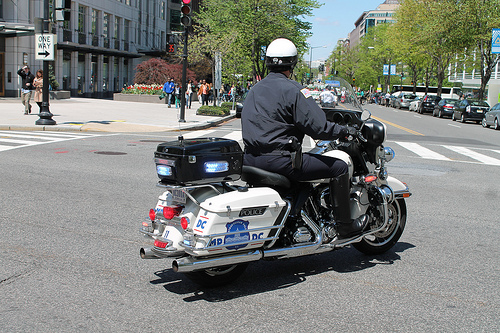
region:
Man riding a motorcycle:
[144, 33, 414, 277]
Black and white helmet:
[265, 30, 299, 73]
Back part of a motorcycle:
[140, 140, 265, 291]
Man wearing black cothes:
[241, 38, 388, 247]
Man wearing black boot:
[241, 39, 376, 237]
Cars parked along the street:
[382, 89, 499, 136]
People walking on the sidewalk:
[161, 73, 243, 115]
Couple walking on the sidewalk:
[16, 60, 43, 120]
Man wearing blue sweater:
[161, 78, 176, 98]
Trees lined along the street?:
[348, 0, 494, 105]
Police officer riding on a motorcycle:
[141, 37, 411, 277]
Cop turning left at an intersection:
[137, 35, 414, 277]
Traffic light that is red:
[175, 0, 194, 122]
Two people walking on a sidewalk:
[15, 61, 45, 118]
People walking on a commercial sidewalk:
[158, 75, 235, 110]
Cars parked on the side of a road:
[392, 89, 498, 130]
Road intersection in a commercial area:
[0, 70, 497, 332]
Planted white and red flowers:
[112, 80, 169, 102]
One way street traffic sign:
[34, 30, 57, 60]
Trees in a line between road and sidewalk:
[330, 0, 499, 102]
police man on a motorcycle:
[138, 36, 411, 296]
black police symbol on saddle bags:
[237, 204, 269, 217]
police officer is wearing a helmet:
[243, 36, 370, 256]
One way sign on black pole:
[34, 30, 57, 127]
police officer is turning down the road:
[139, 38, 496, 318]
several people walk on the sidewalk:
[0, 63, 239, 135]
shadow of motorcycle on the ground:
[149, 242, 416, 307]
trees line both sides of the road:
[199, 2, 492, 122]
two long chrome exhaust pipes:
[137, 241, 332, 274]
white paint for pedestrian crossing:
[381, 135, 497, 169]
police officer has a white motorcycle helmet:
[262, 39, 299, 57]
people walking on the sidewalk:
[151, 66, 249, 112]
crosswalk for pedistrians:
[0, 115, 105, 152]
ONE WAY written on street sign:
[33, 30, 56, 59]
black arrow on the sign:
[36, 45, 51, 56]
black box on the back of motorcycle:
[154, 129, 248, 178]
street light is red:
[179, 0, 197, 33]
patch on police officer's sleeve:
[291, 84, 321, 100]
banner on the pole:
[485, 26, 498, 55]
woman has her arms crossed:
[34, 69, 44, 102]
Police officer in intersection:
[163, 19, 387, 273]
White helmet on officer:
[260, 25, 305, 74]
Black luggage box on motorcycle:
[150, 135, 252, 187]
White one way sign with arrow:
[25, 35, 73, 62]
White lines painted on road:
[385, 125, 495, 185]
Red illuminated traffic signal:
[182, 1, 207, 118]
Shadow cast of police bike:
[105, 220, 415, 305]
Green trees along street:
[200, 5, 283, 102]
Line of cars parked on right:
[326, 80, 498, 140]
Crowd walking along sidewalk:
[151, 77, 234, 106]